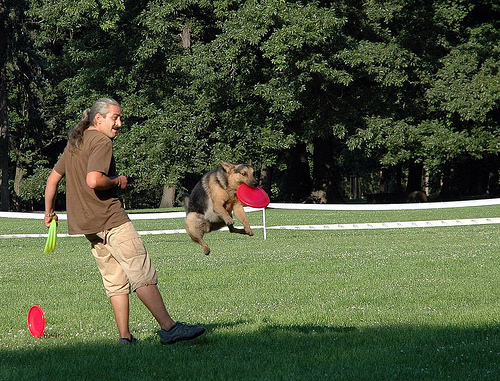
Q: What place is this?
A: It is a field.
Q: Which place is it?
A: It is a field.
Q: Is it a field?
A: Yes, it is a field.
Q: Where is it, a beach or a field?
A: It is a field.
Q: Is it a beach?
A: No, it is a field.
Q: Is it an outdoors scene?
A: Yes, it is outdoors.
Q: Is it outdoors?
A: Yes, it is outdoors.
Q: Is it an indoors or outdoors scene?
A: It is outdoors.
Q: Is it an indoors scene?
A: No, it is outdoors.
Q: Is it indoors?
A: No, it is outdoors.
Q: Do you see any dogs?
A: Yes, there is a dog.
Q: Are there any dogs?
A: Yes, there is a dog.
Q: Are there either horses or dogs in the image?
A: Yes, there is a dog.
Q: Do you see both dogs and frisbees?
A: Yes, there are both a dog and a frisbee.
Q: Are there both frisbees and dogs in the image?
A: Yes, there are both a dog and a frisbee.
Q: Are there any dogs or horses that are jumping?
A: Yes, the dog is jumping.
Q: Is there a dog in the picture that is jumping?
A: Yes, there is a dog that is jumping.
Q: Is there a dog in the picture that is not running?
A: Yes, there is a dog that is jumping.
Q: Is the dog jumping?
A: Yes, the dog is jumping.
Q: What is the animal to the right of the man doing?
A: The dog is jumping.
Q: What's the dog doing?
A: The dog is jumping.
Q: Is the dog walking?
A: No, the dog is jumping.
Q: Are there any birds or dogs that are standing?
A: No, there is a dog but it is jumping.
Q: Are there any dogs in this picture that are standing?
A: No, there is a dog but it is jumping.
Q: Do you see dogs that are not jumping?
A: No, there is a dog but it is jumping.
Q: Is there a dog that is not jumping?
A: No, there is a dog but it is jumping.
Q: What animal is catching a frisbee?
A: The dog is catching a frisbee.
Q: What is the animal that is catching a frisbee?
A: The animal is a dog.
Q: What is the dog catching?
A: The dog is catching a frisbee.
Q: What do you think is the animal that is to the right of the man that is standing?
A: The animal is a dog.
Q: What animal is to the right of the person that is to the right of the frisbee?
A: The animal is a dog.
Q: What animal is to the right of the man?
A: The animal is a dog.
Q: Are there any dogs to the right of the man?
A: Yes, there is a dog to the right of the man.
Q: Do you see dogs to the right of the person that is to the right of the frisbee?
A: Yes, there is a dog to the right of the man.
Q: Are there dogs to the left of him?
A: No, the dog is to the right of the man.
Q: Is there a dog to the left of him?
A: No, the dog is to the right of the man.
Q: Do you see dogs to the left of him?
A: No, the dog is to the right of the man.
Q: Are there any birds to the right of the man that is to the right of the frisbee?
A: No, there is a dog to the right of the man.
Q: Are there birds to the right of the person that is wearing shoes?
A: No, there is a dog to the right of the man.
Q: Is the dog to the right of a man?
A: Yes, the dog is to the right of a man.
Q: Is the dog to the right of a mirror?
A: No, the dog is to the right of a man.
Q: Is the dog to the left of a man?
A: No, the dog is to the right of a man.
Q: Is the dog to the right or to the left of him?
A: The dog is to the right of the man.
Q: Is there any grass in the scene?
A: Yes, there is grass.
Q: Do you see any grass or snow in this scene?
A: Yes, there is grass.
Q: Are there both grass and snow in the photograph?
A: No, there is grass but no snow.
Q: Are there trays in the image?
A: No, there are no trays.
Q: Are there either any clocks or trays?
A: No, there are no trays or clocks.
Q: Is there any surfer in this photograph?
A: No, there are no surfers.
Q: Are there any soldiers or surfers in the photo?
A: No, there are no surfers or soldiers.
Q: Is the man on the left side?
A: Yes, the man is on the left of the image.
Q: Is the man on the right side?
A: No, the man is on the left of the image.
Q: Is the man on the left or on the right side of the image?
A: The man is on the left of the image.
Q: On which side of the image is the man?
A: The man is on the left of the image.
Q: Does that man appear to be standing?
A: Yes, the man is standing.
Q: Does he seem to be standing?
A: Yes, the man is standing.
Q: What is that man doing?
A: The man is standing.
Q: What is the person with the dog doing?
A: The man is standing.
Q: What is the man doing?
A: The man is standing.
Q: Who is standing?
A: The man is standing.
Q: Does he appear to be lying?
A: No, the man is standing.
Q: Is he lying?
A: No, the man is standing.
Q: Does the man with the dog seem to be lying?
A: No, the man is standing.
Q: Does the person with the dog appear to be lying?
A: No, the man is standing.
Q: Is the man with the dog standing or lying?
A: The man is standing.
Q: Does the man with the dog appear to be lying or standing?
A: The man is standing.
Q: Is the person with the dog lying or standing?
A: The man is standing.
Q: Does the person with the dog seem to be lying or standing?
A: The man is standing.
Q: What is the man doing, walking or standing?
A: The man is standing.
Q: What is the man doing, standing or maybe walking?
A: The man is standing.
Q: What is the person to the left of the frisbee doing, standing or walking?
A: The man is standing.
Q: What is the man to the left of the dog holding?
A: The man is holding the frisbee.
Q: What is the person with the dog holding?
A: The man is holding the frisbee.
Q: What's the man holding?
A: The man is holding the frisbee.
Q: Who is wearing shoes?
A: The man is wearing shoes.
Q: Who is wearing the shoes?
A: The man is wearing shoes.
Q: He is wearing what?
A: The man is wearing shoes.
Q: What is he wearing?
A: The man is wearing shoes.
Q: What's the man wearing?
A: The man is wearing shoes.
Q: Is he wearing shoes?
A: Yes, the man is wearing shoes.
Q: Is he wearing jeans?
A: No, the man is wearing shoes.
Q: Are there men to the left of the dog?
A: Yes, there is a man to the left of the dog.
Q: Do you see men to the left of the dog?
A: Yes, there is a man to the left of the dog.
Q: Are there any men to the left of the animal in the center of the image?
A: Yes, there is a man to the left of the dog.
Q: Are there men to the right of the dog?
A: No, the man is to the left of the dog.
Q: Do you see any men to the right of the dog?
A: No, the man is to the left of the dog.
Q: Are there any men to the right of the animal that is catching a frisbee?
A: No, the man is to the left of the dog.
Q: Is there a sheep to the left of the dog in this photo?
A: No, there is a man to the left of the dog.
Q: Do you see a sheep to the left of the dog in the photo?
A: No, there is a man to the left of the dog.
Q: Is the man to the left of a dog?
A: Yes, the man is to the left of a dog.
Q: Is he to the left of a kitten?
A: No, the man is to the left of a dog.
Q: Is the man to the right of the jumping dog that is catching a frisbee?
A: No, the man is to the left of the dog.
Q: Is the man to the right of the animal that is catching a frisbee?
A: No, the man is to the left of the dog.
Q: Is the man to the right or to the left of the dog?
A: The man is to the left of the dog.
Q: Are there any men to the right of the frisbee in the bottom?
A: Yes, there is a man to the right of the frisbee.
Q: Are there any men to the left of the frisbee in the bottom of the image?
A: No, the man is to the right of the frisbee.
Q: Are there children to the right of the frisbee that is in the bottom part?
A: No, there is a man to the right of the frisbee.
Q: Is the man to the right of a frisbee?
A: Yes, the man is to the right of a frisbee.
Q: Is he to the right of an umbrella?
A: No, the man is to the right of a frisbee.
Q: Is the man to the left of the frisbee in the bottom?
A: No, the man is to the right of the frisbee.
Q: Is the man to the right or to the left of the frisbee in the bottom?
A: The man is to the right of the frisbee.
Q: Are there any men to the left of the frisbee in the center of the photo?
A: Yes, there is a man to the left of the frisbee.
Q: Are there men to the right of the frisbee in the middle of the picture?
A: No, the man is to the left of the frisbee.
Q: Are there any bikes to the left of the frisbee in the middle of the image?
A: No, there is a man to the left of the frisbee.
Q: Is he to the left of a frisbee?
A: Yes, the man is to the left of a frisbee.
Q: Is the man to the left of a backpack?
A: No, the man is to the left of a frisbee.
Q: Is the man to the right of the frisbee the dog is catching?
A: No, the man is to the left of the frisbee.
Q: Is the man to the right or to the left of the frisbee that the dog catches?
A: The man is to the left of the frisbee.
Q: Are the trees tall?
A: Yes, the trees are tall.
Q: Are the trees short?
A: No, the trees are tall.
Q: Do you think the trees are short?
A: No, the trees are tall.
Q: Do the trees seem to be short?
A: No, the trees are tall.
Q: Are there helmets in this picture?
A: No, there are no helmets.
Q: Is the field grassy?
A: Yes, the field is grassy.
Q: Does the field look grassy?
A: Yes, the field is grassy.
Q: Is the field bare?
A: No, the field is grassy.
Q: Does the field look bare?
A: No, the field is grassy.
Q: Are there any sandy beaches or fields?
A: No, there is a field but it is grassy.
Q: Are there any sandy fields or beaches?
A: No, there is a field but it is grassy.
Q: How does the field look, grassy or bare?
A: The field is grassy.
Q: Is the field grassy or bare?
A: The field is grassy.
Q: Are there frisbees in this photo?
A: Yes, there is a frisbee.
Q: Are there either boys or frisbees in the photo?
A: Yes, there is a frisbee.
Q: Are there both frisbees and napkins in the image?
A: No, there is a frisbee but no napkins.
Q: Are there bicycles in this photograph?
A: No, there are no bicycles.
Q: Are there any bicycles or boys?
A: No, there are no bicycles or boys.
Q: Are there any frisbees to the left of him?
A: Yes, there is a frisbee to the left of the man.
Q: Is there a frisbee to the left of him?
A: Yes, there is a frisbee to the left of the man.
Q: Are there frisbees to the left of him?
A: Yes, there is a frisbee to the left of the man.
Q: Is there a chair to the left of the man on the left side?
A: No, there is a frisbee to the left of the man.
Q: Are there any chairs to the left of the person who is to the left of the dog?
A: No, there is a frisbee to the left of the man.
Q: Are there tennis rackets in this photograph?
A: No, there are no tennis rackets.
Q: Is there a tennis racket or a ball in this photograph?
A: No, there are no rackets or balls.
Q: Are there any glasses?
A: No, there are no glasses.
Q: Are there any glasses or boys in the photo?
A: No, there are no glasses or boys.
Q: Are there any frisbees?
A: Yes, there is a frisbee.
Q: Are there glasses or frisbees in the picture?
A: Yes, there is a frisbee.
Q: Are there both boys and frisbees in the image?
A: No, there is a frisbee but no boys.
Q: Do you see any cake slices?
A: No, there are no cake slices.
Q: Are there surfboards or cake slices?
A: No, there are no cake slices or surfboards.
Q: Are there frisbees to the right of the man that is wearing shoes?
A: Yes, there is a frisbee to the right of the man.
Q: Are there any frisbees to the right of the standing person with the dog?
A: Yes, there is a frisbee to the right of the man.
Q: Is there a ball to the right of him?
A: No, there is a frisbee to the right of the man.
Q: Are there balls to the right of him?
A: No, there is a frisbee to the right of the man.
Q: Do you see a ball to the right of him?
A: No, there is a frisbee to the right of the man.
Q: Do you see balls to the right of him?
A: No, there is a frisbee to the right of the man.